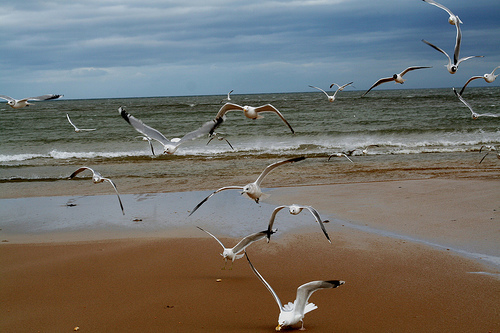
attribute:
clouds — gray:
[2, 5, 137, 52]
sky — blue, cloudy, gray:
[1, 0, 499, 99]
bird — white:
[358, 61, 433, 103]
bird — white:
[243, 252, 353, 330]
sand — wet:
[338, 178, 498, 332]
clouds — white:
[2, 0, 499, 92]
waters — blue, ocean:
[4, 95, 496, 169]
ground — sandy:
[53, 243, 165, 331]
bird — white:
[112, 103, 230, 158]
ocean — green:
[1, 82, 497, 209]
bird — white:
[178, 214, 287, 274]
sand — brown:
[319, 167, 454, 252]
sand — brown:
[9, 250, 204, 326]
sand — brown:
[346, 248, 498, 328]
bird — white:
[266, 199, 333, 249]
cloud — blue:
[4, 7, 441, 72]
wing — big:
[253, 95, 301, 137]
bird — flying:
[213, 101, 295, 138]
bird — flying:
[362, 63, 433, 95]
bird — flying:
[306, 80, 354, 104]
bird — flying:
[187, 155, 321, 218]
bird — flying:
[68, 164, 125, 214]